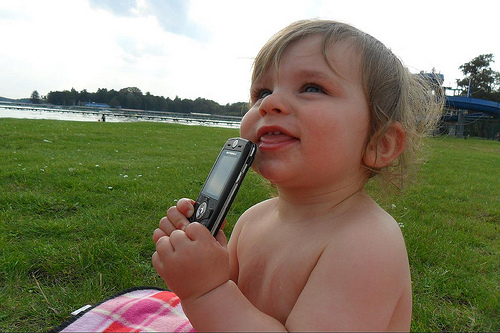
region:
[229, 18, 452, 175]
child has brown hair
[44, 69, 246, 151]
trees off in distance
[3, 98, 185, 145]
water in front of trees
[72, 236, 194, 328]
pink blanket in front of child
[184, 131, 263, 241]
child holds cell phone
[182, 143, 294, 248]
phone is black and silver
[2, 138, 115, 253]
grass is green and thick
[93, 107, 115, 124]
person in distance near water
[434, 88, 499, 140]
blue roof on building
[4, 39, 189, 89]
sky has few clouds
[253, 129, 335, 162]
toddler's mouth is open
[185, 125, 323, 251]
toddler is holding the cellphone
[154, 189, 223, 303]
toddle is holding cellphone with two hands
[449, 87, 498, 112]
roof is blue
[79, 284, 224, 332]
toddler is sitting on a blanket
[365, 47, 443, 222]
toddler has curly hair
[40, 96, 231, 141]
person standing by the water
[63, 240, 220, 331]
blanket is in the grass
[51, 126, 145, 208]
white flowers in the grass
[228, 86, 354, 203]
toddler is smiling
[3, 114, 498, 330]
The grass is green.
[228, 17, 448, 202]
The baby has hair.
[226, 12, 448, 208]
Baby's hair is short.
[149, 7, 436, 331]
The baby is smiling.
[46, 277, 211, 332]
The blanket is plaid.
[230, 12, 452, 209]
The baby has teeth.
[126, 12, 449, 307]
The baby is holding a cell phone.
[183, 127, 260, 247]
The cell phone is black.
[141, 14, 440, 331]
The baby is shirtless.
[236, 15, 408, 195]
The baby has two eyes.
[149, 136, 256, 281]
Cell phone in baby's hands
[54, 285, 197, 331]
Pink red and white blanket on the grass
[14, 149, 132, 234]
Green grass near water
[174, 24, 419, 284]
Baby holding a cell phone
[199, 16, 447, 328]
Baby wearing no shirt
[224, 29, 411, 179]
Baby with tongue sticking out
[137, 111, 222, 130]
pier in the water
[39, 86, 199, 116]
Line of trees in the distance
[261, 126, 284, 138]
Two small baby teeth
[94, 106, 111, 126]
Person standing by the water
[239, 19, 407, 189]
Baby looking up at the sky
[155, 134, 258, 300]
Baby holding a cellphone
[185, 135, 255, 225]
Black cellphone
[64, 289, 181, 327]
Pink and white checkered blanket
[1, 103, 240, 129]
Pier going across the water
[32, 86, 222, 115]
Row of trees in the distance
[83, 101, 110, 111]
House in the distance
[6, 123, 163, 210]
Soft green grass and wildflowers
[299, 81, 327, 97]
Baby's bright blue eyes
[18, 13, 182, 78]
White clouds in the sky